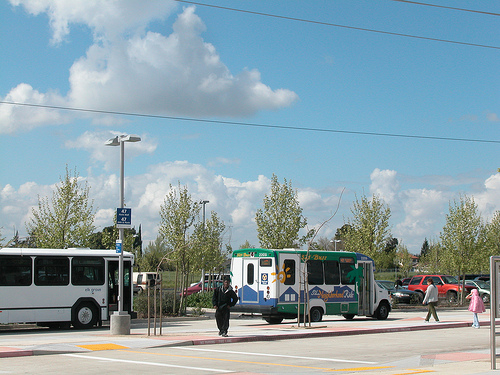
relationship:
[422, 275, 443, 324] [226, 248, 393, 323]
woman walking to bus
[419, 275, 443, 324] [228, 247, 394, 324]
woman walking towards tempo van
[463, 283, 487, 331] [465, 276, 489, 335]
girl in dress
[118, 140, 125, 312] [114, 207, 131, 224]
post with sign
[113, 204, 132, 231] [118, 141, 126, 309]
sign on post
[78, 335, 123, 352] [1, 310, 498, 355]
paint on sidewalk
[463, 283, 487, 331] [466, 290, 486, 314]
girl with dress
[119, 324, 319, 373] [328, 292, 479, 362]
cross walk area on street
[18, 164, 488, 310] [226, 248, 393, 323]
trees behind bus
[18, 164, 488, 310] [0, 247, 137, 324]
trees behind bus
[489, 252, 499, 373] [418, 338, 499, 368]
sign in corner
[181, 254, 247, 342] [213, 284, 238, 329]
man wearing dress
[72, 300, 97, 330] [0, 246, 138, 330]
tire of city bus